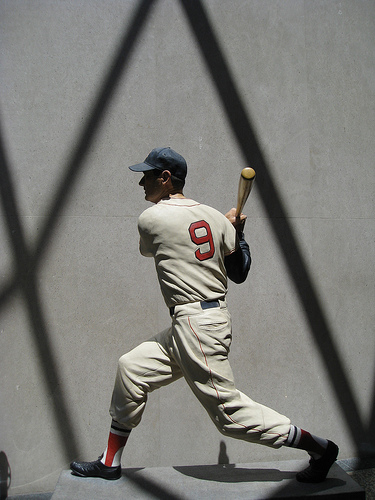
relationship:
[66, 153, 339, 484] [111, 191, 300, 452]
baseball player wearing uniform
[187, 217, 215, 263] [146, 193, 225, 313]
number in back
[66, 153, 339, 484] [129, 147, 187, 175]
baseball player wearing cap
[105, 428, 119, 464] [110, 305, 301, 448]
line in pants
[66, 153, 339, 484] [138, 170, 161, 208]
baseball player has face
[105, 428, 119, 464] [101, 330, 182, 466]
line down side of leg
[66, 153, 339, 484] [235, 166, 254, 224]
baseball player holding bat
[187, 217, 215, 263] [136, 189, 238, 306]
number in shirt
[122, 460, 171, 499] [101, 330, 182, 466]
shadow from leg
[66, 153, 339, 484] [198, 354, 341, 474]
baseball player has leg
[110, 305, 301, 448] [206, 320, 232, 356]
pants have pocket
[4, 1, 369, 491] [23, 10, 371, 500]
shadow in background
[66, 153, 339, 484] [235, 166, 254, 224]
baseball player wearing bat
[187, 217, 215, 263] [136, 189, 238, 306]
number on shirt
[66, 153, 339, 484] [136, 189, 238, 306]
baseball player wearing shirt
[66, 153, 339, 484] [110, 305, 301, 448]
baseball player wearing pants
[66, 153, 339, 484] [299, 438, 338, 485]
baseball player wearing shoe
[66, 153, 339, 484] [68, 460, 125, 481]
baseball player wearing shoe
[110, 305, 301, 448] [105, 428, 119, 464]
pants are wearing line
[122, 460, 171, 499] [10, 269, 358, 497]
shadow on ground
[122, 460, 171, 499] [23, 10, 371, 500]
shadow on background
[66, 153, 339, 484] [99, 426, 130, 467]
baseball player wearing sock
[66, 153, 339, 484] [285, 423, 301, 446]
baseball player wearing sock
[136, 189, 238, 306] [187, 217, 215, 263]
shirt have number